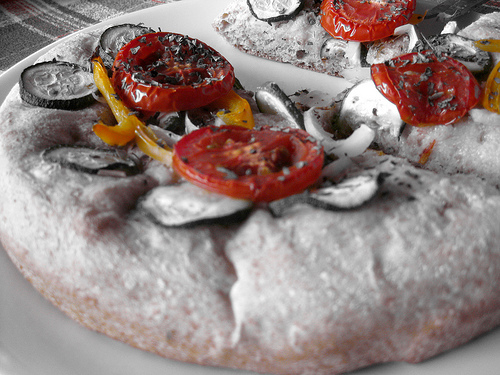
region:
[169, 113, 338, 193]
This is a slice of tomato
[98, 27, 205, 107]
This is a slice of tomato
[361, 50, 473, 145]
This is a slice of tomato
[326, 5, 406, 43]
This is a slice of tomato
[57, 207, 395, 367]
this is a piece of pizza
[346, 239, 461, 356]
this is a piece of pizza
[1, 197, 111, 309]
this is a piece of pizza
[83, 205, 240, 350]
this is a piece of pizza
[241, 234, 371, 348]
this is a piece of pizza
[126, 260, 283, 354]
this is a piece of pizza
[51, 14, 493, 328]
a small size of pizza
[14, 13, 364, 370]
a homemade pizza putted at the white plate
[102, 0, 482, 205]
a four red tomatoes on the top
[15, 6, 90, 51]
checkered cloth placed at the table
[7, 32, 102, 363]
the plate of the pizza is color white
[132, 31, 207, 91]
basil put at the top of the tomatoes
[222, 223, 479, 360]
white sprinkled on the bread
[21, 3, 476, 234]
the pizza was sliced into two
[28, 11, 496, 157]
differerent veggies put on the top of the bread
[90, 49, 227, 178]
a yellow piece of tomato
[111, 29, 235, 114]
Tomato slice that has been cooked.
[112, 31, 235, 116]
Cooked tomato is red with burnt flesh.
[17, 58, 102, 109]
Cucumber slice located on the bread.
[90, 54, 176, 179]
Slice yellow pepper located on the bread.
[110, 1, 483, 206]
There are four red tomato slices on the bread.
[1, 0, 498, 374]
Round flat bread cut in half.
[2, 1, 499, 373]
Bread is on a plate.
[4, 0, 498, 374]
Plate is white in color.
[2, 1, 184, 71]
Grey and white plaid cloth on table.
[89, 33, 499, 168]
Multiple yellow peppers located on bread.